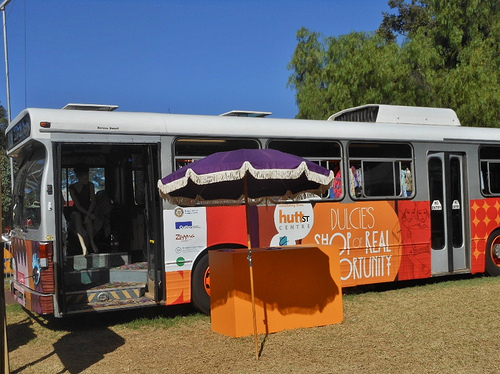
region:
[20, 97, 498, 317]
colorful bus parked next to a stand and umbrella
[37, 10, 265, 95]
very clear and very blue sky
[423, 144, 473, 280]
closed back doors of the bus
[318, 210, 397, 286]
white writing on orange on the side of the bus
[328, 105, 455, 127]
air conditioning unit on top of the bus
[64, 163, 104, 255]
lady sitting sideways in the driver's seat of the bus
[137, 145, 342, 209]
blue umbrella with a white fringed trim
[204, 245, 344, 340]
orange wooden stand next to the umbrella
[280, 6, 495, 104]
green tall tree behind the bus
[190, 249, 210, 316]
side of the black front wheel on the bus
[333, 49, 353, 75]
leaves on the tree.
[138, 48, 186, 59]
blue sky above bus.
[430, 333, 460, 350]
grass on the ground.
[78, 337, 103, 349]
shadow on the grass.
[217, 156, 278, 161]
umbrella on a pole.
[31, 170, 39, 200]
windshield on the bus.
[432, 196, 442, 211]
logo on the door.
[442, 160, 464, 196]
door of the bus.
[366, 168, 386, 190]
window on the bus.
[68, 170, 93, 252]
person inside the bus.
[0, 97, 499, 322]
A bus parked on the grass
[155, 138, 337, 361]
A purple shade umbrella with white fringe and support pole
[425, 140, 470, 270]
Glass and metal back doors to a bus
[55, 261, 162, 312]
The step going into a bus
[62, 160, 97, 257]
A woman with her hands crossed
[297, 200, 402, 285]
An orange circular sign with white letters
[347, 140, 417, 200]
The window of a bus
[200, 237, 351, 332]
The shadow of a shade umbrella and pole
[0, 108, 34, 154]
The destination sign on the top front of a bus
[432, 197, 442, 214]
A white sign with black lettering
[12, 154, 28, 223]
window of a bus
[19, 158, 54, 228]
window of a bus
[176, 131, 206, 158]
window of a bus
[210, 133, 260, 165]
window of a bus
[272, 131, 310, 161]
window of a bus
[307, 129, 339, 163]
window of a bus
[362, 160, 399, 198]
window of a bus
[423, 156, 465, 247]
window of a bus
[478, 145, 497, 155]
window of a bus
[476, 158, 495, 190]
window of a bus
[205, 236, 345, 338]
an orange booth beside a bus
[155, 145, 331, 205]
a purple umbrella next to a bus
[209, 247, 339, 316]
the shadow of an umbrella on an orange booth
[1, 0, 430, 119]
a clear blue sky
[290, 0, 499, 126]
a green leafy tree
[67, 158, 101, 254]
a woma seated in the front of a bus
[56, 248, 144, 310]
steps inside a bus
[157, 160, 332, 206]
a white fringe on a purple umbrella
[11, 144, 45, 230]
the front window of a bus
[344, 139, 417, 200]
a window on the side of a bus